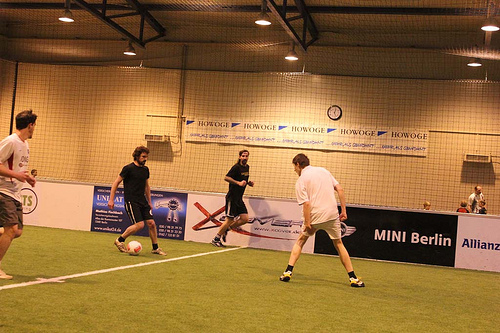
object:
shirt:
[295, 165, 340, 226]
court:
[0, 225, 499, 332]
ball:
[127, 240, 142, 256]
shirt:
[118, 161, 150, 202]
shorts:
[123, 200, 153, 224]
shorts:
[0, 193, 24, 226]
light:
[123, 51, 136, 56]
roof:
[0, 1, 499, 81]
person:
[280, 153, 365, 286]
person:
[106, 146, 166, 256]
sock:
[348, 269, 358, 279]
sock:
[285, 264, 295, 272]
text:
[442, 239, 452, 246]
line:
[0, 245, 248, 291]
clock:
[326, 105, 343, 121]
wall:
[1, 59, 499, 215]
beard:
[136, 157, 147, 165]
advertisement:
[90, 184, 190, 241]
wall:
[23, 179, 500, 274]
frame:
[326, 105, 343, 120]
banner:
[180, 115, 431, 156]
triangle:
[186, 119, 196, 125]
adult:
[468, 186, 486, 213]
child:
[456, 200, 470, 213]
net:
[1, 0, 498, 214]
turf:
[1, 223, 499, 332]